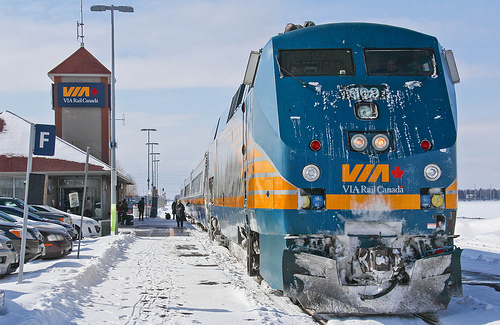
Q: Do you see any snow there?
A: Yes, there is snow.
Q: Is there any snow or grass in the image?
A: Yes, there is snow.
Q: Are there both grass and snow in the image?
A: No, there is snow but no grass.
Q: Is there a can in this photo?
A: No, there are no cans.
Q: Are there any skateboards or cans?
A: No, there are no cans or skateboards.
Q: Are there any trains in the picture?
A: Yes, there is a train.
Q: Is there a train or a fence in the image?
A: Yes, there is a train.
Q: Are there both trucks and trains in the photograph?
A: No, there is a train but no trucks.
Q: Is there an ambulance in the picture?
A: No, there are no ambulances.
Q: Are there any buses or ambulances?
A: No, there are no ambulances or buses.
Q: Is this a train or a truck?
A: This is a train.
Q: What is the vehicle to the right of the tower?
A: The vehicle is a train.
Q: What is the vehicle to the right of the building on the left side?
A: The vehicle is a train.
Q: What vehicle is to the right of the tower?
A: The vehicle is a train.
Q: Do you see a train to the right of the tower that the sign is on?
A: Yes, there is a train to the right of the tower.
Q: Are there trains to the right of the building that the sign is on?
A: Yes, there is a train to the right of the tower.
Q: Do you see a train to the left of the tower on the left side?
A: No, the train is to the right of the tower.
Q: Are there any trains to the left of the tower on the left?
A: No, the train is to the right of the tower.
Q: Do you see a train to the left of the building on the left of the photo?
A: No, the train is to the right of the tower.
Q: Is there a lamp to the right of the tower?
A: No, there is a train to the right of the tower.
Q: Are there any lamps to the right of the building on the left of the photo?
A: No, there is a train to the right of the tower.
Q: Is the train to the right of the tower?
A: Yes, the train is to the right of the tower.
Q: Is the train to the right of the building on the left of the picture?
A: Yes, the train is to the right of the tower.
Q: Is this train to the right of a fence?
A: No, the train is to the right of the tower.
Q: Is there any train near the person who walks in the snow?
A: Yes, there is a train near the person.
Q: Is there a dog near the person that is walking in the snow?
A: No, there is a train near the person.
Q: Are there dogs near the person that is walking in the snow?
A: No, there is a train near the person.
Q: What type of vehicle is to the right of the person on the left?
A: The vehicle is a train.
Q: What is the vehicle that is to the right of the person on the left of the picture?
A: The vehicle is a train.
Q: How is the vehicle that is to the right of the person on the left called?
A: The vehicle is a train.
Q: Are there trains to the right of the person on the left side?
A: Yes, there is a train to the right of the person.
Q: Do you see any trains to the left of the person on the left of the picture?
A: No, the train is to the right of the person.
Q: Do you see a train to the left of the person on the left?
A: No, the train is to the right of the person.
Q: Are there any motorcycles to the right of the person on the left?
A: No, there is a train to the right of the person.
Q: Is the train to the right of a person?
A: Yes, the train is to the right of a person.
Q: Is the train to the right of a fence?
A: No, the train is to the right of a person.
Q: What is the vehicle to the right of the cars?
A: The vehicle is a train.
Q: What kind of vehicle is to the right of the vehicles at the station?
A: The vehicle is a train.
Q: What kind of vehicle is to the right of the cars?
A: The vehicle is a train.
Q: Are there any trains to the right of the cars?
A: Yes, there is a train to the right of the cars.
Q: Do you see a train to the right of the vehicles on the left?
A: Yes, there is a train to the right of the cars.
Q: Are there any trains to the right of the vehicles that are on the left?
A: Yes, there is a train to the right of the cars.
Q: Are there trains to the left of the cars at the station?
A: No, the train is to the right of the cars.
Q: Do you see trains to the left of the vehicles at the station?
A: No, the train is to the right of the cars.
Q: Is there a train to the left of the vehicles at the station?
A: No, the train is to the right of the cars.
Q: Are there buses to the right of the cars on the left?
A: No, there is a train to the right of the cars.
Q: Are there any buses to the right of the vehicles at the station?
A: No, there is a train to the right of the cars.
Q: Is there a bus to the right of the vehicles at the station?
A: No, there is a train to the right of the cars.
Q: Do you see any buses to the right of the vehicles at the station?
A: No, there is a train to the right of the cars.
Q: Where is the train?
A: The train is in the snow.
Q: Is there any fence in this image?
A: No, there are no fences.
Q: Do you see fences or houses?
A: No, there are no fences or houses.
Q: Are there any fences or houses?
A: No, there are no fences or houses.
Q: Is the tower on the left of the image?
A: Yes, the tower is on the left of the image.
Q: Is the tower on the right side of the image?
A: No, the tower is on the left of the image.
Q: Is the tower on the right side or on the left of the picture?
A: The tower is on the left of the image.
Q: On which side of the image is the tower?
A: The tower is on the left of the image.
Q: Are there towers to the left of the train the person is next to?
A: Yes, there is a tower to the left of the train.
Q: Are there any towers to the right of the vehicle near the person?
A: No, the tower is to the left of the train.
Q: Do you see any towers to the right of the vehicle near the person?
A: No, the tower is to the left of the train.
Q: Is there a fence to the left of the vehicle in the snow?
A: No, there is a tower to the left of the train.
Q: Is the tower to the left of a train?
A: Yes, the tower is to the left of a train.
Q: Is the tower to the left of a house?
A: No, the tower is to the left of a train.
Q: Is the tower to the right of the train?
A: No, the tower is to the left of the train.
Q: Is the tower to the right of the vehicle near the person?
A: No, the tower is to the left of the train.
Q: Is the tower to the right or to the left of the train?
A: The tower is to the left of the train.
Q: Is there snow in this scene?
A: Yes, there is snow.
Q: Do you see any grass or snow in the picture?
A: Yes, there is snow.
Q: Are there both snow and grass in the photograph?
A: No, there is snow but no grass.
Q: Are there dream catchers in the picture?
A: No, there are no dream catchers.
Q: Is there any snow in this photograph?
A: Yes, there is snow.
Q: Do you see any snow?
A: Yes, there is snow.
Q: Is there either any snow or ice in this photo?
A: Yes, there is snow.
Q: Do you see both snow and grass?
A: No, there is snow but no grass.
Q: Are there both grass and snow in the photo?
A: No, there is snow but no grass.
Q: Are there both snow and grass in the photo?
A: No, there is snow but no grass.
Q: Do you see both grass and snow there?
A: No, there is snow but no grass.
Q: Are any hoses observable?
A: No, there are no hoses.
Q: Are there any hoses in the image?
A: No, there are no hoses.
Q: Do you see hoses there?
A: No, there are no hoses.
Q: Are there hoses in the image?
A: No, there are no hoses.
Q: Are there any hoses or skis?
A: No, there are no hoses or skis.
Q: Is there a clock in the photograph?
A: No, there are no clocks.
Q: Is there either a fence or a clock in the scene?
A: No, there are no clocks or fences.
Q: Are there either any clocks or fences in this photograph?
A: No, there are no clocks or fences.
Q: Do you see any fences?
A: No, there are no fences.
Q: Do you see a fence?
A: No, there are no fences.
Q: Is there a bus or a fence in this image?
A: No, there are no fences or buses.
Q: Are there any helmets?
A: No, there are no helmets.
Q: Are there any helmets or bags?
A: No, there are no helmets or bags.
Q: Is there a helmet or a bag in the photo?
A: No, there are no helmets or bags.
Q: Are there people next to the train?
A: Yes, there is a person next to the train.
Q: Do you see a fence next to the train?
A: No, there is a person next to the train.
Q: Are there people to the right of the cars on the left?
A: Yes, there is a person to the right of the cars.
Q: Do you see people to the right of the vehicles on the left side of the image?
A: Yes, there is a person to the right of the cars.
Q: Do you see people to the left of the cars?
A: No, the person is to the right of the cars.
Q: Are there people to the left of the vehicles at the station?
A: No, the person is to the right of the cars.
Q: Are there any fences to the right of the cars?
A: No, there is a person to the right of the cars.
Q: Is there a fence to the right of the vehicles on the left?
A: No, there is a person to the right of the cars.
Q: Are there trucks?
A: No, there are no trucks.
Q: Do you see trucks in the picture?
A: No, there are no trucks.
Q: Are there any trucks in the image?
A: No, there are no trucks.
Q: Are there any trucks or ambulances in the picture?
A: No, there are no trucks or ambulances.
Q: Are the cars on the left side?
A: Yes, the cars are on the left of the image.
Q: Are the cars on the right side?
A: No, the cars are on the left of the image.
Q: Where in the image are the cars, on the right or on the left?
A: The cars are on the left of the image.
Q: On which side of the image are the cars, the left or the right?
A: The cars are on the left of the image.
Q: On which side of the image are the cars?
A: The cars are on the left of the image.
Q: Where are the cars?
A: The cars are at the station.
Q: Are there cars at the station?
A: Yes, there are cars at the station.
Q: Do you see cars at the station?
A: Yes, there are cars at the station.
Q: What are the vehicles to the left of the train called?
A: The vehicles are cars.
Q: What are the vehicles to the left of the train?
A: The vehicles are cars.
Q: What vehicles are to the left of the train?
A: The vehicles are cars.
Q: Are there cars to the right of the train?
A: No, the cars are to the left of the train.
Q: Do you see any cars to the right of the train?
A: No, the cars are to the left of the train.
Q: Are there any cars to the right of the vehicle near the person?
A: No, the cars are to the left of the train.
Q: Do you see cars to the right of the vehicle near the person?
A: No, the cars are to the left of the train.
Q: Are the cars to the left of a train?
A: Yes, the cars are to the left of a train.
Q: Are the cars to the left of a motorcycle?
A: No, the cars are to the left of a train.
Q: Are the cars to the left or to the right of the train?
A: The cars are to the left of the train.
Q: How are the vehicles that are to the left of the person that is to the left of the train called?
A: The vehicles are cars.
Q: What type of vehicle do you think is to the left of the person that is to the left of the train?
A: The vehicles are cars.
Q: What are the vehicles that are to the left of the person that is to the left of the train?
A: The vehicles are cars.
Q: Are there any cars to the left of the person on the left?
A: Yes, there are cars to the left of the person.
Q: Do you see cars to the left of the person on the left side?
A: Yes, there are cars to the left of the person.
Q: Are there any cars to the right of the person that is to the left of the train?
A: No, the cars are to the left of the person.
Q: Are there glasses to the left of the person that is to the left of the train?
A: No, there are cars to the left of the person.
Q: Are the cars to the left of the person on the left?
A: Yes, the cars are to the left of the person.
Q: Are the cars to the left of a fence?
A: No, the cars are to the left of the person.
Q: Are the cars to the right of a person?
A: No, the cars are to the left of a person.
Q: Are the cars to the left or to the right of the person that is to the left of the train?
A: The cars are to the left of the person.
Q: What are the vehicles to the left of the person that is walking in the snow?
A: The vehicles are cars.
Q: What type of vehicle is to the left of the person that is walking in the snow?
A: The vehicles are cars.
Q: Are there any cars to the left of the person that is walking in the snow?
A: Yes, there are cars to the left of the person.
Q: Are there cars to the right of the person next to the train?
A: No, the cars are to the left of the person.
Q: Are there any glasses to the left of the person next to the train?
A: No, there are cars to the left of the person.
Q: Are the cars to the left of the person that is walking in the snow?
A: Yes, the cars are to the left of the person.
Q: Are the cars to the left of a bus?
A: No, the cars are to the left of the person.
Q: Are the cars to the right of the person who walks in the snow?
A: No, the cars are to the left of the person.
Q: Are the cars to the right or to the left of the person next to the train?
A: The cars are to the left of the person.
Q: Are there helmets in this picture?
A: No, there are no helmets.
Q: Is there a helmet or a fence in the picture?
A: No, there are no helmets or fences.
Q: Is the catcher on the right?
A: Yes, the catcher is on the right of the image.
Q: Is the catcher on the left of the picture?
A: No, the catcher is on the right of the image.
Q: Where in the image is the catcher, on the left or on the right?
A: The catcher is on the right of the image.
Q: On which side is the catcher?
A: The catcher is on the right of the image.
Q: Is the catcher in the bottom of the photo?
A: Yes, the catcher is in the bottom of the image.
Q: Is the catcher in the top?
A: No, the catcher is in the bottom of the image.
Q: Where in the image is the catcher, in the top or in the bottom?
A: The catcher is in the bottom of the image.